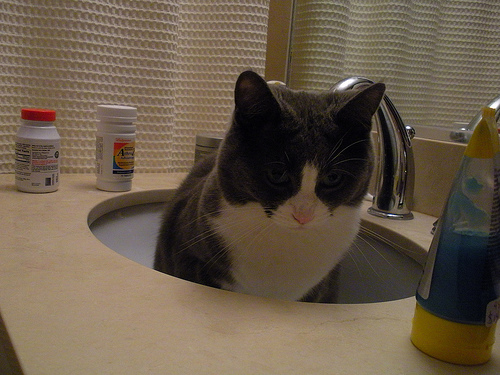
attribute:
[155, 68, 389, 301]
cat — sitting, gray, white, grey, seated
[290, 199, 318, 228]
nose — pink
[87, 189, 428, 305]
sink — bathroom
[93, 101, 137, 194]
bottle — white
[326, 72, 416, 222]
faucet — silver, chrome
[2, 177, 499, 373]
counter top — tan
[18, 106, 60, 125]
cap — red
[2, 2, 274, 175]
curtain — mini, white, patterned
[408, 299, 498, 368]
lid — yellow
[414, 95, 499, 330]
tube — blue